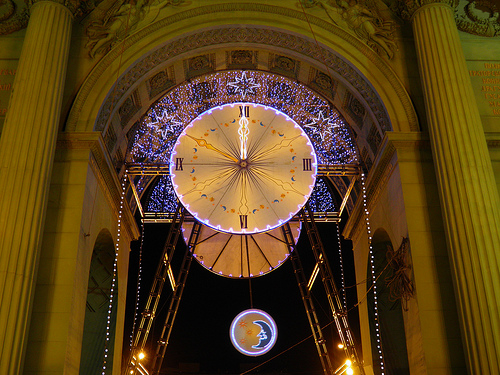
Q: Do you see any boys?
A: No, there are no boys.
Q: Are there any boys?
A: No, there are no boys.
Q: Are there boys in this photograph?
A: No, there are no boys.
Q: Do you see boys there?
A: No, there are no boys.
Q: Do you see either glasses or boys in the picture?
A: No, there are no boys or glasses.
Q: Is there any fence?
A: No, there are no fences.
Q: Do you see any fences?
A: No, there are no fences.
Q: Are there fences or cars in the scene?
A: No, there are no fences or cars.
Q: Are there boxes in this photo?
A: No, there are no boxes.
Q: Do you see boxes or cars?
A: No, there are no boxes or cars.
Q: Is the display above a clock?
A: Yes, the display is above a clock.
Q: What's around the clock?
A: The display is around the clock.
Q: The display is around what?
A: The display is around the clock.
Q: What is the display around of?
A: The display is around the clock.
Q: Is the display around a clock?
A: Yes, the display is around a clock.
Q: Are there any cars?
A: No, there are no cars.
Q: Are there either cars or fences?
A: No, there are no cars or fences.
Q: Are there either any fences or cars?
A: No, there are no cars or fences.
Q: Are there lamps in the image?
A: No, there are no lamps.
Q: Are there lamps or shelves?
A: No, there are no lamps or shelves.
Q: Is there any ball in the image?
A: No, there are no balls.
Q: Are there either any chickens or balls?
A: No, there are no balls or chickens.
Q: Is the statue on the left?
A: Yes, the statue is on the left of the image.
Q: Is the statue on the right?
A: No, the statue is on the left of the image.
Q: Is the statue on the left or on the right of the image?
A: The statue is on the left of the image.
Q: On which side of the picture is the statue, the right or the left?
A: The statue is on the left of the image.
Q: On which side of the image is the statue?
A: The statue is on the left of the image.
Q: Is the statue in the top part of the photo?
A: Yes, the statue is in the top of the image.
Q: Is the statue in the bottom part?
A: No, the statue is in the top of the image.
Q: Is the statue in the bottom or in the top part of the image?
A: The statue is in the top of the image.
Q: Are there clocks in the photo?
A: Yes, there is a clock.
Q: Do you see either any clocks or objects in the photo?
A: Yes, there is a clock.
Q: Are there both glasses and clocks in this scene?
A: No, there is a clock but no glasses.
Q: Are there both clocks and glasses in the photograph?
A: No, there is a clock but no glasses.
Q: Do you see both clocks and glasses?
A: No, there is a clock but no glasses.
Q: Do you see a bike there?
A: No, there are no bikes.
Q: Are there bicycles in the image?
A: No, there are no bicycles.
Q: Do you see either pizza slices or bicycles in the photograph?
A: No, there are no bicycles or pizza slices.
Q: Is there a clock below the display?
A: Yes, there is a clock below the display.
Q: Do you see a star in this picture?
A: Yes, there is a star.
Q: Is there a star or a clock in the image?
A: Yes, there is a star.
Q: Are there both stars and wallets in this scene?
A: No, there is a star but no wallets.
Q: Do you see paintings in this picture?
A: No, there are no paintings.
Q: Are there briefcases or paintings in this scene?
A: No, there are no paintings or briefcases.